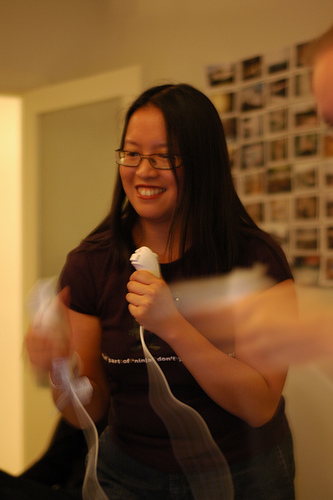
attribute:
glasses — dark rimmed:
[114, 146, 182, 171]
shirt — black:
[61, 236, 288, 455]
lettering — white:
[97, 348, 180, 365]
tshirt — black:
[48, 205, 299, 494]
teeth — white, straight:
[134, 187, 166, 197]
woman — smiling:
[29, 81, 302, 498]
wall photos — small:
[199, 54, 332, 211]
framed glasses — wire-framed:
[107, 143, 185, 170]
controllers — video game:
[3, 245, 225, 365]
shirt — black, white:
[26, 218, 298, 498]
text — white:
[106, 353, 155, 368]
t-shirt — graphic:
[72, 258, 140, 378]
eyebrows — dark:
[108, 139, 182, 159]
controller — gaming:
[130, 244, 164, 279]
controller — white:
[128, 245, 160, 279]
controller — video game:
[30, 292, 80, 348]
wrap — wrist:
[35, 350, 84, 390]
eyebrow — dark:
[151, 134, 176, 156]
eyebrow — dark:
[120, 132, 146, 153]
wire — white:
[137, 351, 214, 449]